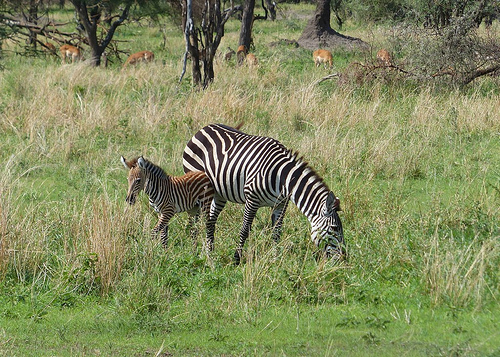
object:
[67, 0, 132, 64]
tree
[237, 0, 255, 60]
tree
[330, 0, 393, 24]
bush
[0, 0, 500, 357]
grass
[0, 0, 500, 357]
landscape